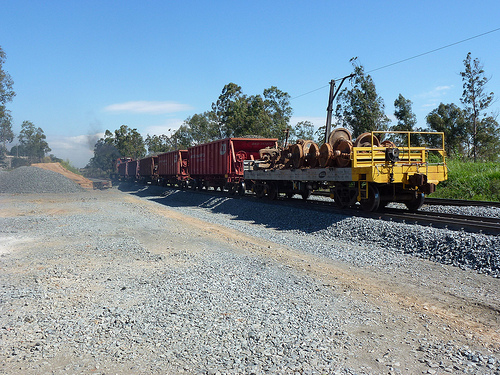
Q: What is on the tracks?
A: A train.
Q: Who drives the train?
A: A conductor.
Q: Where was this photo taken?
A: Outside on the tracks.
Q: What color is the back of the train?
A: Yellow.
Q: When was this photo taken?
A: During the day.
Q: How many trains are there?
A: One.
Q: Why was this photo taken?
A: To show the train.